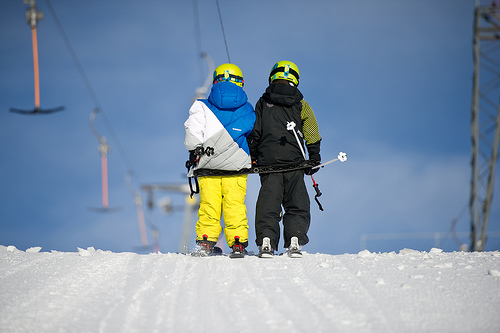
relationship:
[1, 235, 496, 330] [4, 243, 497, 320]
snow covers ground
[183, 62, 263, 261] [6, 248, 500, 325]
skier at ski slope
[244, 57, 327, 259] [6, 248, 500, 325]
skier at ski slope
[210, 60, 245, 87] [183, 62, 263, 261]
helmet worn by skier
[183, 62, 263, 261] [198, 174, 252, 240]
skier wearing snowpants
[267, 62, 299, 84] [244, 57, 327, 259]
helmet worn by skier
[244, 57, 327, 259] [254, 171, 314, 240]
skier wearing pants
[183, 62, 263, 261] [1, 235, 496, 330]
skier on snow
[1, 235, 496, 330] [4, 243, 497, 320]
snow on ground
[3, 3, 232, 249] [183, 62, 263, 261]
ski lift left of skier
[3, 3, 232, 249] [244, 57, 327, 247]
ski lift left of skier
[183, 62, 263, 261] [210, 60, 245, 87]
skier has helmet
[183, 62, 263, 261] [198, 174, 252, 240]
skier has snowpants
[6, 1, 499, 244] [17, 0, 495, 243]
sky in distance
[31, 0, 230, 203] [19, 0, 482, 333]
wire in air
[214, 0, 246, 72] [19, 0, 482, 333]
wire in air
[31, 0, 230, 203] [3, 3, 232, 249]
wire for ski lift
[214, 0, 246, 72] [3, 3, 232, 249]
wire for ski lift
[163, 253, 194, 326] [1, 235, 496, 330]
ski track in snow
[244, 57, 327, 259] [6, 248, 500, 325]
skier at slope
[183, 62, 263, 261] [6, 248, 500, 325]
skier at slope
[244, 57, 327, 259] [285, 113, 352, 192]
skier holding poles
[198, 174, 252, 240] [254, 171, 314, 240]
snowpants contrast pants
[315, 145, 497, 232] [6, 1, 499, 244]
clouds in sky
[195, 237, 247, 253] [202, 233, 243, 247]
boots with trim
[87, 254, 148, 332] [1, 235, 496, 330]
track in snow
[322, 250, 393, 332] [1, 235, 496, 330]
track in snow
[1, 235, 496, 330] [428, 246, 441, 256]
snow has part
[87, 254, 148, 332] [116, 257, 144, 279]
track has part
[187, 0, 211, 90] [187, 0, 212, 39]
line has part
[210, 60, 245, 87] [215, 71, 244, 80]
helmet has part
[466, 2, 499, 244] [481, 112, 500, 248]
post has part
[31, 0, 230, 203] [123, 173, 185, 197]
wire has part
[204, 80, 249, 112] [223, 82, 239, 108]
hood has part